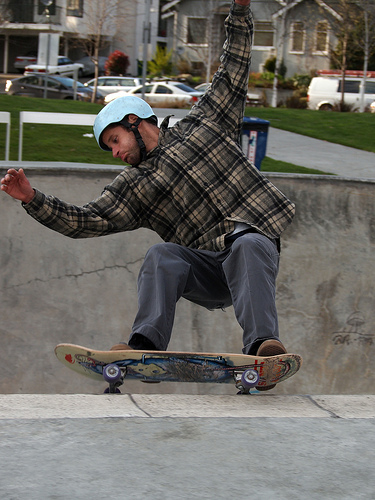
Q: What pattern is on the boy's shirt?
A: Plaid.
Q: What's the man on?
A: Skateboard.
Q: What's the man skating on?
A: Skateboard.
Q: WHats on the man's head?
A: Helmet.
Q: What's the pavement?
A: Concrete.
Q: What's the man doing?
A: Tricks.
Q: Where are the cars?
A: Background.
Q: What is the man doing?
A: Skateboard tricks.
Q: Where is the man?
A: A skateboard park in a neighborhood.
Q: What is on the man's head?
A: A helmet.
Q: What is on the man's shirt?
A: Plaid.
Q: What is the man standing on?
A: A skateboard.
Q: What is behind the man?
A: Parked cars.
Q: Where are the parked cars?
A: On the street.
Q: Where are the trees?
A: Side of the street.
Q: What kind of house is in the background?
A: Two story.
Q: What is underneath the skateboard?
A: Wheels.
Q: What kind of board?
A: Skateboard.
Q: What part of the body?
A: Leg.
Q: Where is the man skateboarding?
A: Halfpipe.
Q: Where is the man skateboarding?
A: Halfpipe.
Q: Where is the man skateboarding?
A: Halfpipe.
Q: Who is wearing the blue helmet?
A: Male skateboarder.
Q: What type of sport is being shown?
A: Skateboarding.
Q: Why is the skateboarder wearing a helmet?
A: For safety.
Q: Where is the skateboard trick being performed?
A: On a halfpipe.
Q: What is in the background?
A: Houses.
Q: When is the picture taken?
A: Daytime.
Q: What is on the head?
A: A helmet.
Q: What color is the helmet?
A: Light blue.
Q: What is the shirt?
A: A flannel.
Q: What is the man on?
A: A skateboard.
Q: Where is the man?
A: On the skateboard.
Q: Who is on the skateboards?
A: A man.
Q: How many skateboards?
A: One.